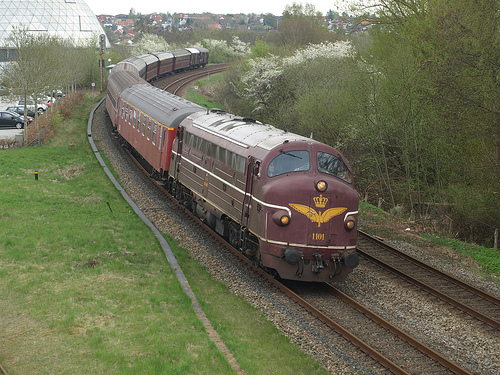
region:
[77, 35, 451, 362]
this is a train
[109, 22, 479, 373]
train on the tracks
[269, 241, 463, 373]
this is a train track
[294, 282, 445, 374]
train tracks are rusted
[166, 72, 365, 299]
maroon lead train car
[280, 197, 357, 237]
yellow wings on front of train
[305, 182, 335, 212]
yellow crown on train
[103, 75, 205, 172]
a red train car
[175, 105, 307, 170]
white roof of train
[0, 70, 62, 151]
cars parked in a parking lot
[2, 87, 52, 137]
cars in a parking lot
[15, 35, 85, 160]
trees in front of the cars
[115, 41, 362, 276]
a train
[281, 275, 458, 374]
the rail road tracks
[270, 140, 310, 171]
the window on the train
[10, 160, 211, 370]
the grass next to the train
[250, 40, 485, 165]
trees behind the train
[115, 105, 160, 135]
windows on the side of the train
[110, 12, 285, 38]
houses in the distance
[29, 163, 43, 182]
A small black with yellow post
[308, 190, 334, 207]
A golden crown sign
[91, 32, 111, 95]
A tall signal light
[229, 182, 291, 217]
A white line at the side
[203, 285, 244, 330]
Green grass beside the tracks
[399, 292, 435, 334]
There are small stone in the railways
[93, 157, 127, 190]
A gray steel on the grass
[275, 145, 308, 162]
A small wiper at the top the glass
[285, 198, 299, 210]
Tip of the birds' golden wing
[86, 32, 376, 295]
a passenger train travelling down the tracks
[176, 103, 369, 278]
the locomotive of a train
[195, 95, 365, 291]
the engine of a train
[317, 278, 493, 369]
the rails of a train track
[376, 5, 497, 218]
the foliage of several deciduous trees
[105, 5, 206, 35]
several houses on a hillside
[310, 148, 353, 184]
the windshield on a train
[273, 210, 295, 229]
the headlight on a train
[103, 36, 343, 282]
a train on a track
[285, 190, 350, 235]
a symbol on the front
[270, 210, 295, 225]
a light on a train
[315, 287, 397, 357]
a rusty rail road track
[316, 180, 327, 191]
a head light on a train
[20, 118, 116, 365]
green grass by a track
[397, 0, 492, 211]
a bunch of leafy green trees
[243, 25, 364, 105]
white trees in bloom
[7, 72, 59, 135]
cars in a parking lot